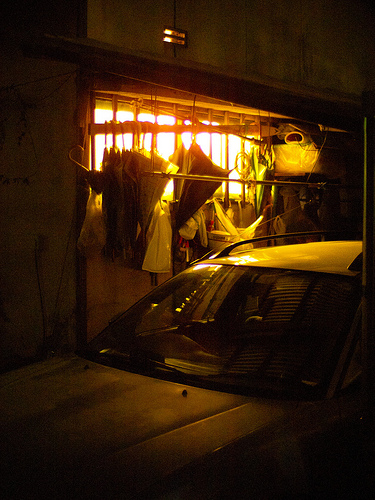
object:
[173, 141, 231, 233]
umbrellas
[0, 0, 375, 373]
wall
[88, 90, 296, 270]
light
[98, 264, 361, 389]
reflection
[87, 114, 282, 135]
rod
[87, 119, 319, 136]
pole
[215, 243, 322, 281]
cover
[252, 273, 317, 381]
line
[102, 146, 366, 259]
rail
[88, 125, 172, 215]
stand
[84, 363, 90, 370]
hole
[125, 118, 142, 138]
hand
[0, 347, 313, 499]
bonnet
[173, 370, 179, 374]
wipers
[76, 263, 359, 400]
screen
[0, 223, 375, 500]
automobile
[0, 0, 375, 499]
garage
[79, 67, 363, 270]
window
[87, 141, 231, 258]
umbrella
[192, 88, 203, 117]
handle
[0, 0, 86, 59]
vent